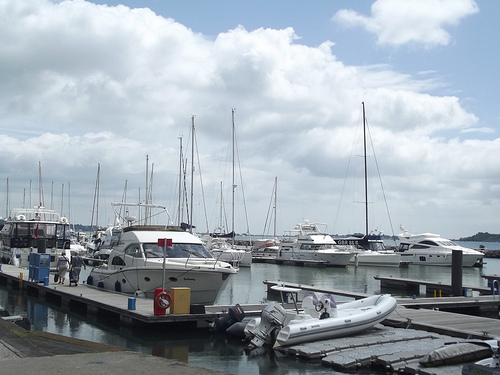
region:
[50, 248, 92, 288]
two people walking on the dock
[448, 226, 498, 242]
large hill on the water's edge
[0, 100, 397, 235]
many masts of sail boats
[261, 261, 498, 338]
wooden planked boat docks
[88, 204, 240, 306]
beautiful white docked boat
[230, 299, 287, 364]
grey metal boat motor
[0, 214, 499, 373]
small harbor full of docked boats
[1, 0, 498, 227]
cloudy sky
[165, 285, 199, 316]
yellow box on the dock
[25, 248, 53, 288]
large blue boxes on the dock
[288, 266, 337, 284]
the water is still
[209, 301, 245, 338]
the engine is small and black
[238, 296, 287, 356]
the engine is big and gray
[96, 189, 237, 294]
the yuaght is docked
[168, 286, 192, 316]
the box is yellow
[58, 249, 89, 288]
the people are holding hands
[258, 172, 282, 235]
the sail is down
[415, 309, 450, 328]
the dock is wooden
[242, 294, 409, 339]
the boat is small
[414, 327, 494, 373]
a body bag for a fish funeral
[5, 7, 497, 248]
Sky is cloudy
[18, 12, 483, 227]
It's day time in photo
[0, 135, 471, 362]
Various yachts in water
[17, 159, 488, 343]
All yachts are white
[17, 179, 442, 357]
The waters are calm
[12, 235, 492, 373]
Bridges are in this photo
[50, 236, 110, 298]
Two people on bridge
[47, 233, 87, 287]
The people are walking here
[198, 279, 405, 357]
This is a smaller boat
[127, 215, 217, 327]
Red and yellow are the colors here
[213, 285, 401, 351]
small boat parked on the dock.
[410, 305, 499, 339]
Dock made with wood planks.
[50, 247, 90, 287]
Two people walking along the dock.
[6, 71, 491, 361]
Several boats parked in the marina.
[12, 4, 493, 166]
Blue sky filled with fluffy clouds.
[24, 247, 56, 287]
Blue postal boxes for drop off.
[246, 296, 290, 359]
large motor of the boat raised out of the water.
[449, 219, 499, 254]
Shoreline in the distance of the marina.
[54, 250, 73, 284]
Woman holding a black bag.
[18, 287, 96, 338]
Reflection of items in the dock area n the water.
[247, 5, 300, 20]
this is the sky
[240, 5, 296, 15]
the sky is blue in color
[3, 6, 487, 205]
the sky is full of clouds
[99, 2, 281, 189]
the clouds are big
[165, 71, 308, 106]
the clouds are white in color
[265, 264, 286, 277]
this is the water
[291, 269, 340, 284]
the water is clear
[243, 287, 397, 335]
this is a lifesaver boat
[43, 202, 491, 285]
these are several boats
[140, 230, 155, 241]
the boat is white in color